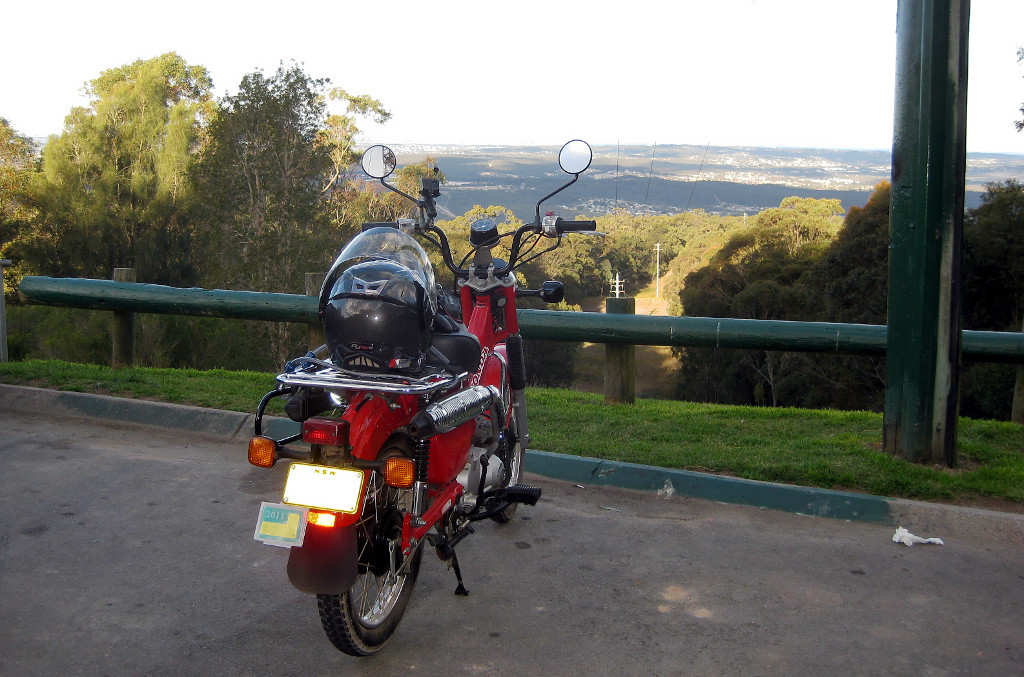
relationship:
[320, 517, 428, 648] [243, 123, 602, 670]
tire on bike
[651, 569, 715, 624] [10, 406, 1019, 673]
sunlight on road